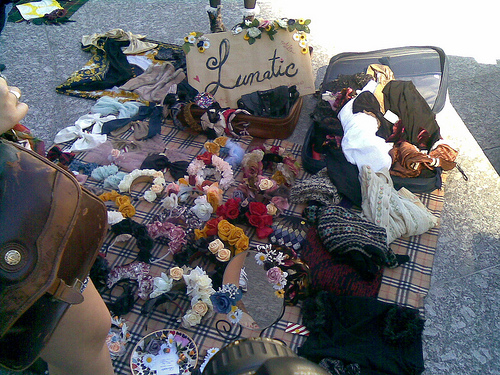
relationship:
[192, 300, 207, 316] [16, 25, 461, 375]
flowers on blanket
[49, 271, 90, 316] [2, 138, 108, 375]
strap of bag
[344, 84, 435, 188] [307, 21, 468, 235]
cloths in suitcase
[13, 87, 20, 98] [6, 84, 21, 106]
ring on finger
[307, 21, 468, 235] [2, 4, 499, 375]
suitcase on ground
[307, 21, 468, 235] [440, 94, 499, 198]
suitcase by curb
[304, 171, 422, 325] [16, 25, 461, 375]
clothes on blanket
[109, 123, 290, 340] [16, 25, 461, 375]
flowers on blanket